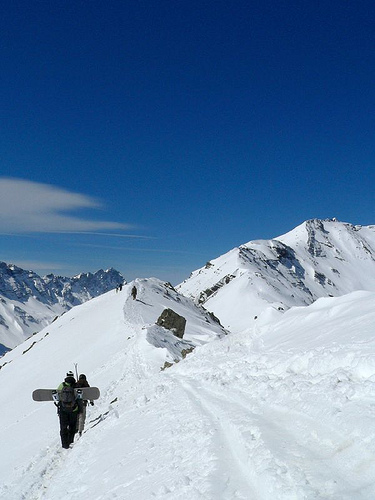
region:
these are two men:
[53, 366, 98, 450]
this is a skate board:
[29, 386, 49, 401]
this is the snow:
[190, 363, 326, 477]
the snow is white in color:
[168, 362, 304, 497]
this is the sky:
[138, 5, 288, 136]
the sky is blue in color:
[152, 23, 312, 141]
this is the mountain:
[224, 238, 294, 299]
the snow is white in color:
[212, 234, 296, 304]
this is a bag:
[58, 387, 76, 408]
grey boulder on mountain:
[121, 287, 197, 356]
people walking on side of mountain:
[0, 255, 186, 498]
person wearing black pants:
[50, 401, 88, 452]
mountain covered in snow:
[1, 205, 372, 499]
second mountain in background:
[3, 245, 125, 351]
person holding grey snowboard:
[29, 384, 104, 404]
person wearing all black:
[130, 283, 140, 303]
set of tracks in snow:
[140, 308, 373, 496]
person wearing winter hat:
[62, 367, 76, 380]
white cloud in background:
[2, 167, 197, 303]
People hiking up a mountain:
[10, 351, 102, 427]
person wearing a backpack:
[55, 380, 83, 419]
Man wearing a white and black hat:
[63, 365, 80, 380]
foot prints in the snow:
[20, 444, 77, 492]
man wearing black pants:
[56, 407, 79, 443]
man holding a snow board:
[28, 384, 100, 403]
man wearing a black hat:
[78, 371, 90, 384]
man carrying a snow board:
[31, 380, 105, 404]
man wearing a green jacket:
[51, 378, 82, 407]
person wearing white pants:
[75, 402, 98, 433]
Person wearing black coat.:
[127, 283, 142, 294]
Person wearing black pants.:
[129, 293, 145, 304]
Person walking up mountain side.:
[122, 281, 150, 302]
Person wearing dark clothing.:
[115, 279, 125, 290]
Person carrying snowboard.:
[23, 388, 106, 411]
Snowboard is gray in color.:
[23, 378, 115, 407]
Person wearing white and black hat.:
[60, 367, 83, 386]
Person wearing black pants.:
[58, 416, 86, 444]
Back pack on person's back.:
[57, 388, 80, 418]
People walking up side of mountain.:
[36, 353, 114, 426]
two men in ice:
[31, 356, 118, 447]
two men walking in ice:
[34, 351, 128, 469]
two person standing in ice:
[26, 360, 152, 478]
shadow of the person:
[89, 414, 117, 428]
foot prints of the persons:
[12, 429, 73, 498]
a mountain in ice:
[129, 283, 193, 345]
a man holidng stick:
[64, 360, 80, 372]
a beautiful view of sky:
[0, 6, 367, 255]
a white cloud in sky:
[14, 166, 97, 252]